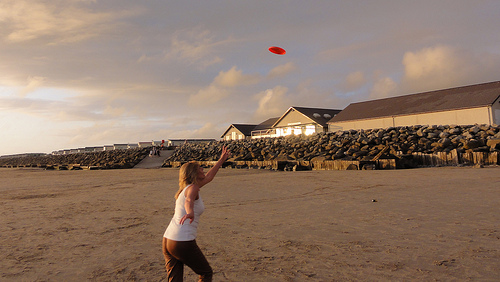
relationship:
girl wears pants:
[146, 144, 227, 281] [160, 240, 213, 280]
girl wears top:
[146, 144, 227, 281] [163, 185, 206, 235]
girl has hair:
[146, 144, 227, 281] [176, 158, 200, 195]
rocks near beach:
[1, 123, 492, 170] [4, 170, 496, 275]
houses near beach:
[41, 139, 216, 156] [4, 170, 496, 275]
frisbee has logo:
[270, 48, 289, 58] [271, 46, 278, 49]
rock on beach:
[371, 199, 378, 205] [4, 170, 496, 275]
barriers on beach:
[182, 151, 494, 167] [4, 170, 496, 275]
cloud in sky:
[183, 66, 299, 113] [7, 1, 498, 154]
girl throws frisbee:
[146, 144, 227, 281] [270, 48, 289, 58]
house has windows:
[256, 109, 345, 138] [272, 126, 315, 135]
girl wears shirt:
[146, 144, 227, 281] [167, 185, 204, 240]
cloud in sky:
[190, 67, 246, 112] [7, 1, 498, 154]